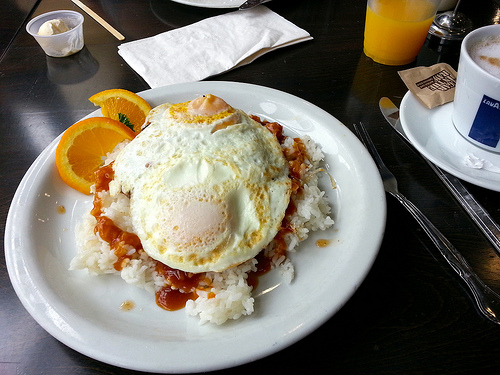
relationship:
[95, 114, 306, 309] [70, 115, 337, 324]
ketchup on rice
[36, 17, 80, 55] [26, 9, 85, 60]
butter in cup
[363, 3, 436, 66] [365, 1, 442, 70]
orange juice in cup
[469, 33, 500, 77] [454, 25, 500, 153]
coffee in mug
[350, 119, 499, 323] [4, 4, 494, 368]
fork on table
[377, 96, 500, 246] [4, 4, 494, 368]
butter knife on table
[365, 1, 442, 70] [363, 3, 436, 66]
cup of orange juice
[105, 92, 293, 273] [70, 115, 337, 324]
egg on rice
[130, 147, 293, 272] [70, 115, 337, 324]
egg on rice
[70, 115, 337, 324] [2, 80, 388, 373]
rice on a plate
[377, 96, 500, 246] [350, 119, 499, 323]
butter knife and fork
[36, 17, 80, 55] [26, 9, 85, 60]
butter in a cup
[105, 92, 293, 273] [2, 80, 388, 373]
egg on a plate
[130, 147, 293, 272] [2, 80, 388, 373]
egg on a plate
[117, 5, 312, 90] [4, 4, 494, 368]
napkin on table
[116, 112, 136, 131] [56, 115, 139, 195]
sprig near orange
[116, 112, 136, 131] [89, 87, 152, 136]
sprig near orange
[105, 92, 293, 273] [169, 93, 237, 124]
egg has a yolk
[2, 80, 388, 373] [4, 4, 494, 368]
plate on table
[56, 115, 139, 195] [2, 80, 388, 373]
orange on plate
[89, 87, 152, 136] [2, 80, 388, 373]
orange on plate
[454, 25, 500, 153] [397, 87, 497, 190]
mug on saucer